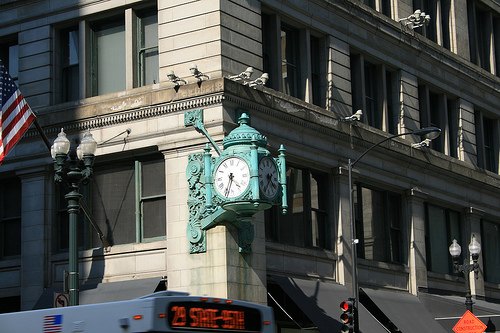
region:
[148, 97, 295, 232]
clock molded to the building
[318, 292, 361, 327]
traffic light is red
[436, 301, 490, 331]
an orange road sign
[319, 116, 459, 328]
black street light pole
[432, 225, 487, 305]
2 lamp street light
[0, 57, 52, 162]
the american flag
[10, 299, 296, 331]
a city bus on the street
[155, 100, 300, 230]
the clock is green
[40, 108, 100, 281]
a green 4 post light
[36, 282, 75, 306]
no left turn sign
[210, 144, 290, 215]
green clock on side of building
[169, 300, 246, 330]
yellow words atop bus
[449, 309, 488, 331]
orange construction sign behind bus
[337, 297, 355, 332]
traffic light lit red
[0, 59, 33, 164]
American flag hanging from building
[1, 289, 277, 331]
white bus in front of building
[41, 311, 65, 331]
American flag on side of bus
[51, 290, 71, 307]
white sign with black arrow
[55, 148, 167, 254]
window on large building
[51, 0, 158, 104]
window on large building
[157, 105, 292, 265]
intricate green metal clock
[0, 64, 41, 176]
american flag on the side of a building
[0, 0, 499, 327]
grey stone building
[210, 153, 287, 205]
two black and white clock faces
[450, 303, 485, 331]
orange road work sign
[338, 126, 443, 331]
black metal street lamp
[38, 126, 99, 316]
three street lights sharing a pole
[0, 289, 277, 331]
white city bus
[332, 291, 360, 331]
illuminated red stop light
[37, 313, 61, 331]
backwards american flag sticker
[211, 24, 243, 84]
edge of a building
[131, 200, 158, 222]
part of a window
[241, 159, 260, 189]
part of a clock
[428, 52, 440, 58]
edge of a building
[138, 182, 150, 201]
part of a window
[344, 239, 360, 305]
section of a wall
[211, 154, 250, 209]
black white and green clock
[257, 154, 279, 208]
black white and green clock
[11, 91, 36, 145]
red white and blue national flag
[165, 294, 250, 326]
orange route sign on bus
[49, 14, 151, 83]
window of tan and brown building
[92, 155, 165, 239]
window of tan and brown building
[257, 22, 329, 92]
window of tan and brown building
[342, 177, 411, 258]
window of tan and brown building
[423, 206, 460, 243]
window of tan and brown building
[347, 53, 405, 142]
window of tan and brown building